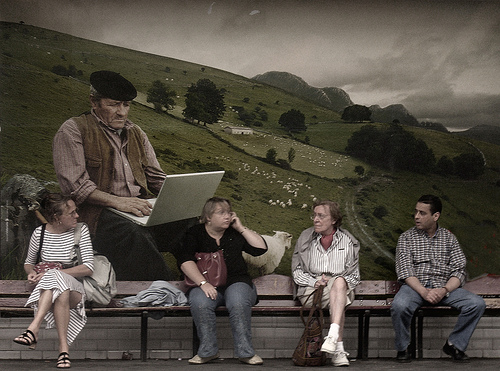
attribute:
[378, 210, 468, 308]
shirt — plaid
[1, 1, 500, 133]
sky — here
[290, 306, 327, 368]
bag — brown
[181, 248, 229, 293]
bag — brown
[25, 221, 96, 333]
dress — white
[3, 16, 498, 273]
grass — green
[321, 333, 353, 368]
shoes — white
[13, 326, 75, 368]
heels — black, sandals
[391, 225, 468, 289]
man — plaid, button down